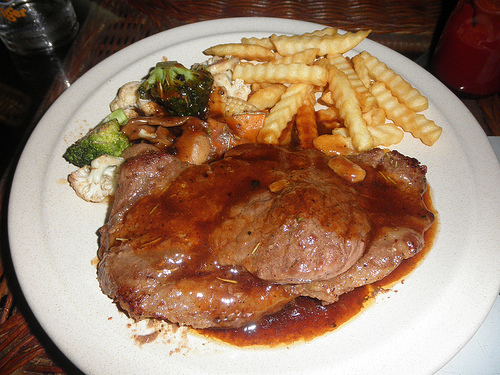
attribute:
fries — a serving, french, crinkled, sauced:
[203, 25, 443, 152]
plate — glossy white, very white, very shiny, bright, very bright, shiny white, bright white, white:
[7, 19, 500, 375]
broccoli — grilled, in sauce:
[136, 61, 211, 116]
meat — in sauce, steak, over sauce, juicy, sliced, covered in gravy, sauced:
[99, 143, 434, 324]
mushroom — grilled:
[126, 115, 191, 148]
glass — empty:
[0, 0, 79, 50]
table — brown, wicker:
[1, 2, 499, 132]